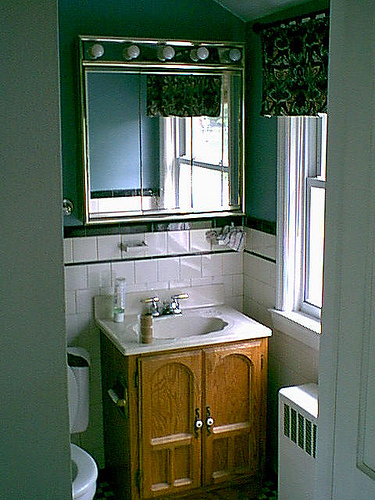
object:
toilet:
[68, 345, 98, 499]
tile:
[127, 248, 201, 285]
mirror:
[81, 67, 246, 223]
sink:
[95, 300, 279, 359]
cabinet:
[100, 316, 270, 500]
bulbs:
[88, 41, 243, 61]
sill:
[272, 306, 326, 353]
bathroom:
[2, 1, 374, 498]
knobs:
[193, 406, 214, 434]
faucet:
[141, 288, 190, 319]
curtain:
[252, 6, 332, 119]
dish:
[113, 239, 155, 259]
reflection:
[139, 78, 222, 122]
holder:
[102, 384, 127, 416]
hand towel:
[204, 225, 254, 256]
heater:
[277, 376, 321, 498]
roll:
[137, 308, 155, 344]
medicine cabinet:
[78, 33, 245, 219]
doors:
[138, 347, 261, 499]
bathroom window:
[284, 115, 328, 327]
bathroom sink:
[132, 297, 232, 340]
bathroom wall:
[69, 238, 261, 293]